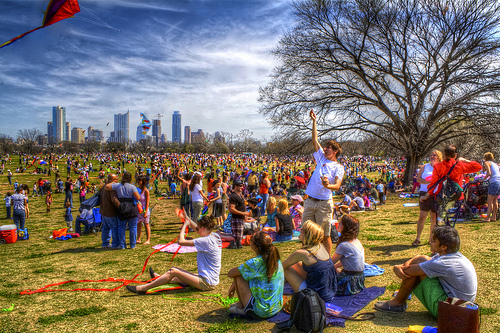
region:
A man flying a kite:
[304, 107, 345, 269]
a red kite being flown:
[1, 1, 90, 55]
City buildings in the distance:
[43, 104, 255, 152]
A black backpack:
[288, 287, 325, 332]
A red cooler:
[0, 223, 21, 245]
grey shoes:
[373, 299, 408, 315]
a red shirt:
[429, 155, 481, 204]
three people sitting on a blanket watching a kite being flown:
[228, 214, 387, 326]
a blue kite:
[136, 113, 156, 140]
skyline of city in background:
[40, 104, 206, 146]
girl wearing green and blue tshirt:
[227, 229, 285, 311]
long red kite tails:
[19, 226, 197, 299]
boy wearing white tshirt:
[300, 109, 347, 207]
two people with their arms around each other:
[97, 169, 142, 239]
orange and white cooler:
[0, 220, 20, 247]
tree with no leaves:
[270, 79, 498, 133]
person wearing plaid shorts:
[229, 174, 244, 253]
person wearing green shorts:
[372, 220, 482, 328]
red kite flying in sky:
[5, 2, 86, 57]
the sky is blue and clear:
[56, 10, 224, 117]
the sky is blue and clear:
[111, 26, 279, 176]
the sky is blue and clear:
[84, 46, 356, 303]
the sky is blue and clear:
[119, 25, 232, 92]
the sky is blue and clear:
[101, 50, 280, 102]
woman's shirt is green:
[234, 244, 309, 319]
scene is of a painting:
[1, 3, 498, 332]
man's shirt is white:
[298, 156, 335, 205]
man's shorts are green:
[412, 279, 467, 321]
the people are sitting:
[141, 204, 498, 329]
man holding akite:
[166, 206, 237, 276]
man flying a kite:
[303, 111, 340, 223]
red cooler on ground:
[0, 216, 32, 257]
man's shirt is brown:
[94, 179, 128, 220]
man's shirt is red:
[429, 161, 477, 198]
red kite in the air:
[3, 0, 89, 62]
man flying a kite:
[276, 90, 339, 256]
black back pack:
[278, 279, 338, 331]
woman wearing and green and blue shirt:
[223, 228, 288, 323]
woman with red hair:
[271, 209, 348, 314]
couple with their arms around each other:
[73, 147, 150, 259]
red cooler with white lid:
[1, 217, 33, 258]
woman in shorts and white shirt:
[399, 143, 458, 253]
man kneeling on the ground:
[216, 174, 260, 249]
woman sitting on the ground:
[111, 188, 234, 300]